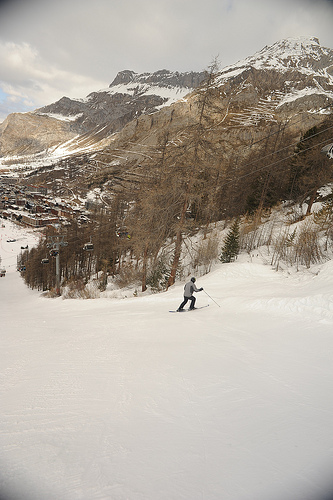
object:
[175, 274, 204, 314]
person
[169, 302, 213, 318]
two skis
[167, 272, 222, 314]
skier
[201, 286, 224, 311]
two ski poles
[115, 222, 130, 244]
ski lift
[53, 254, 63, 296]
tower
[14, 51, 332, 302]
trees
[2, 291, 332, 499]
slope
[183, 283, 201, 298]
jacket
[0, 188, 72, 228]
buildings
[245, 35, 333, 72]
snow covered peaks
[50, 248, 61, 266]
skiers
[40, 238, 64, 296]
ski lift tower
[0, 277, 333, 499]
ski trail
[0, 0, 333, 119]
sky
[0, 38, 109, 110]
clouds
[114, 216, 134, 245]
ski chairs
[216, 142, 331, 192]
cables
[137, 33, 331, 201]
mountains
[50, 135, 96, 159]
ski trails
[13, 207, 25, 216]
roofs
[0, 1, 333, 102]
gray sky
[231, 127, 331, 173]
thin cables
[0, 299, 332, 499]
trail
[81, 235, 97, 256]
lift chairs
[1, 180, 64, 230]
city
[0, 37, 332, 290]
valley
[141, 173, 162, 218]
leeves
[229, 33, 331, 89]
peaks